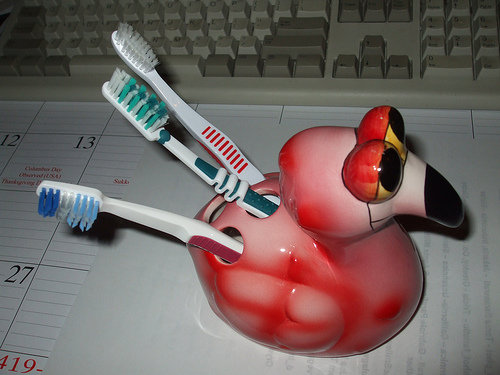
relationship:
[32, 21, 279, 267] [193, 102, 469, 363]
toothbrushes in holder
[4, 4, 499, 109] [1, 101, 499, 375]
keyboard on calendar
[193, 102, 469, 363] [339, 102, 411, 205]
holder has eyes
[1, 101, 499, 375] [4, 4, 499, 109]
calendar under keyboard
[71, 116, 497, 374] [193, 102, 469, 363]
paper under holder